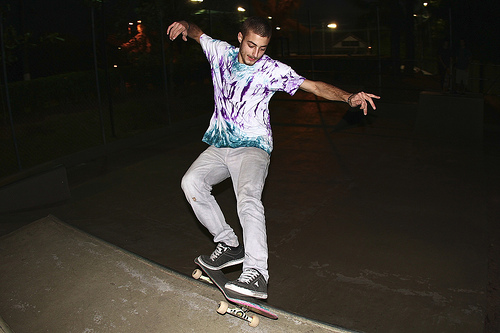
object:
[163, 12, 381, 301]
man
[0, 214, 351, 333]
concrete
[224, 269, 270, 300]
sneakers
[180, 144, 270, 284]
jeans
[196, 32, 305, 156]
shirt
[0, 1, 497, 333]
picture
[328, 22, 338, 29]
light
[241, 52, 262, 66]
facial hair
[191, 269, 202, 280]
wheel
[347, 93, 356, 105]
wristwatch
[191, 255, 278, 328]
skateboard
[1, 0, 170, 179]
fence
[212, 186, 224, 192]
shadow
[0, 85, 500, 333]
ground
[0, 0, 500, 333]
skate park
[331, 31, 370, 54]
house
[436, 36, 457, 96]
kid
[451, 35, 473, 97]
kid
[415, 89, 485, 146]
ramp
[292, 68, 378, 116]
arm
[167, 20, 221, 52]
arm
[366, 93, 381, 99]
finger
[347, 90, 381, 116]
hand